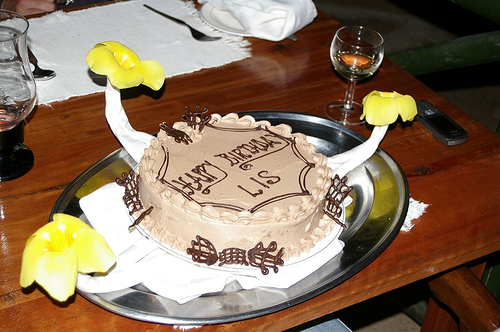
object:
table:
[438, 173, 496, 213]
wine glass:
[321, 22, 388, 124]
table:
[286, 67, 363, 122]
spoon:
[12, 27, 57, 84]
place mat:
[2, 0, 257, 112]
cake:
[157, 120, 361, 205]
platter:
[102, 129, 470, 280]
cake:
[140, 124, 338, 250]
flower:
[75, 34, 180, 194]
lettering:
[174, 128, 301, 201]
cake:
[124, 104, 358, 268]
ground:
[366, 125, 452, 166]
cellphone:
[404, 97, 489, 154]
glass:
[1, 15, 37, 141]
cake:
[148, 92, 358, 289]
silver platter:
[131, 297, 236, 325]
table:
[407, 212, 481, 254]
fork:
[142, 0, 224, 44]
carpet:
[364, 310, 416, 330]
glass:
[314, 10, 393, 162]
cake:
[115, 99, 362, 276]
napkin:
[215, 0, 329, 47]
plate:
[193, 1, 262, 44]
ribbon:
[138, 110, 335, 223]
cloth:
[15, 0, 250, 105]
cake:
[116, 108, 343, 266]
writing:
[211, 127, 285, 174]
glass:
[327, 23, 387, 125]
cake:
[51, 118, 363, 274]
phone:
[410, 97, 470, 147]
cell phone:
[400, 93, 471, 148]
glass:
[322, 17, 390, 129]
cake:
[82, 29, 424, 274]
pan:
[41, 103, 415, 330]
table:
[392, 52, 495, 175]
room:
[2, 4, 498, 327]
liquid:
[335, 54, 376, 77]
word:
[182, 163, 211, 192]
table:
[357, 43, 498, 235]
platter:
[42, 99, 414, 324]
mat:
[6, 4, 253, 109]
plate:
[197, 1, 255, 39]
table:
[6, 4, 498, 324]